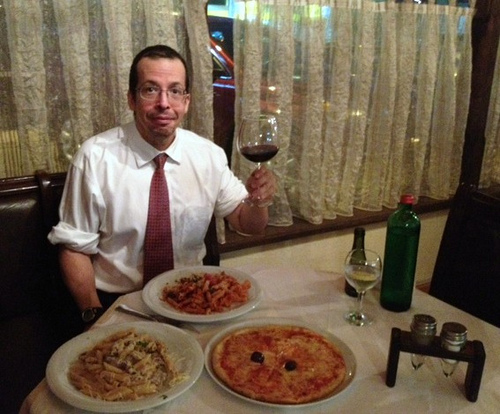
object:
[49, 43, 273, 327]
man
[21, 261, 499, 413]
table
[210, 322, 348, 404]
pizza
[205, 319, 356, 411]
plate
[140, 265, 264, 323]
plate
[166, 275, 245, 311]
pasta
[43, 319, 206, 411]
plate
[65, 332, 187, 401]
pasta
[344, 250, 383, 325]
wine glass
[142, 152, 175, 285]
tie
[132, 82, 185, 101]
glasses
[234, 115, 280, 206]
glass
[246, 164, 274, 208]
hand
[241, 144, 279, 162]
wine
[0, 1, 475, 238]
curtain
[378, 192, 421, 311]
bottle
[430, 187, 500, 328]
chair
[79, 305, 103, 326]
watch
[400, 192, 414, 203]
cap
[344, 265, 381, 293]
wine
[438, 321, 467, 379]
salt & pepper shaker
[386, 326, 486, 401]
holder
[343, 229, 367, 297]
bottle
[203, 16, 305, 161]
car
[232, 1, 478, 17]
edge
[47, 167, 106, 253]
sleeve